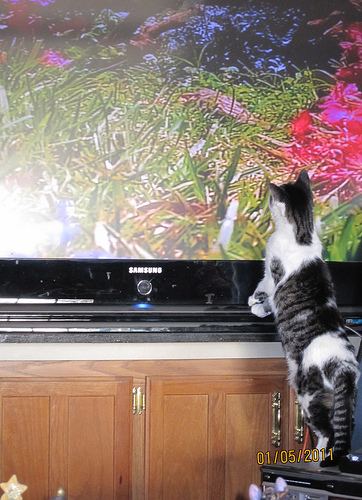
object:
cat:
[248, 168, 360, 468]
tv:
[0, 0, 362, 333]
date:
[256, 447, 334, 465]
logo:
[126, 267, 163, 273]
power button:
[137, 279, 153, 295]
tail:
[320, 371, 351, 467]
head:
[267, 168, 313, 217]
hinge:
[136, 387, 146, 414]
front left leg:
[247, 261, 281, 307]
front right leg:
[251, 296, 277, 318]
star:
[0, 473, 28, 499]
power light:
[134, 302, 150, 309]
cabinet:
[0, 326, 361, 500]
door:
[0, 375, 133, 499]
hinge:
[132, 387, 137, 414]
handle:
[272, 391, 282, 446]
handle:
[294, 397, 304, 444]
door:
[142, 374, 291, 500]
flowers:
[181, 87, 255, 123]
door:
[289, 386, 319, 461]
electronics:
[339, 449, 362, 477]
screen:
[0, 0, 362, 263]